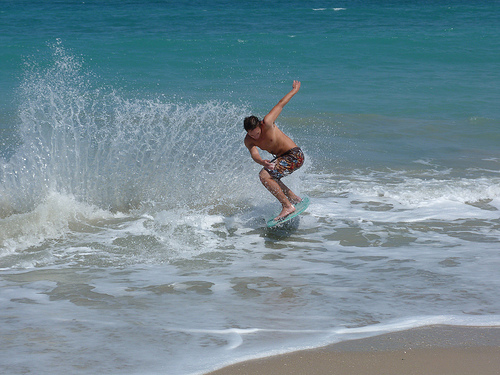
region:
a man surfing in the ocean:
[214, 85, 331, 248]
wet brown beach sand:
[304, 349, 449, 374]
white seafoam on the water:
[226, 316, 271, 352]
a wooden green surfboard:
[279, 200, 303, 224]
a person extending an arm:
[229, 72, 314, 222]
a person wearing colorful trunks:
[233, 92, 328, 224]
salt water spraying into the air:
[37, 65, 224, 174]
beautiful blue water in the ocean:
[21, 0, 487, 123]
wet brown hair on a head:
[246, 112, 260, 126]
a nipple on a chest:
[266, 133, 279, 144]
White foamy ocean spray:
[21, 75, 258, 204]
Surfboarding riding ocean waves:
[19, 25, 471, 356]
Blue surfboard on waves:
[252, 198, 327, 236]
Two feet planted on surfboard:
[255, 191, 318, 227]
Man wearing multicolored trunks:
[232, 110, 314, 184]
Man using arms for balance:
[232, 74, 338, 231]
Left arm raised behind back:
[218, 75, 329, 176]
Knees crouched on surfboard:
[227, 165, 321, 231]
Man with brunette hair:
[231, 105, 273, 146]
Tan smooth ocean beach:
[259, 308, 499, 371]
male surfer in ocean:
[230, 92, 325, 244]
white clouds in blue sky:
[392, 29, 483, 121]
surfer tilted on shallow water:
[208, 57, 485, 367]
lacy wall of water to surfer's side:
[0, 37, 311, 238]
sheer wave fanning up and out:
[2, 40, 242, 222]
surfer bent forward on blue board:
[240, 72, 305, 228]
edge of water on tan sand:
[210, 315, 495, 366]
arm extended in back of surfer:
[240, 71, 315, 231]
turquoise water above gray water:
[65, 20, 485, 145]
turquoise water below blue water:
[15, 5, 495, 85]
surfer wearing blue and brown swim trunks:
[240, 71, 315, 231]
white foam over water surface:
[23, 227, 491, 317]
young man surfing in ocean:
[204, 86, 318, 243]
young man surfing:
[207, 72, 317, 247]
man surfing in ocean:
[220, 46, 312, 254]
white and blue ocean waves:
[18, 25, 73, 105]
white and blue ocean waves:
[64, 101, 141, 193]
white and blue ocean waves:
[17, 185, 85, 260]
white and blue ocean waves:
[130, 185, 191, 243]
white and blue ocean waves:
[115, 28, 165, 78]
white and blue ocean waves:
[208, 36, 250, 71]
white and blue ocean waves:
[328, 0, 368, 80]